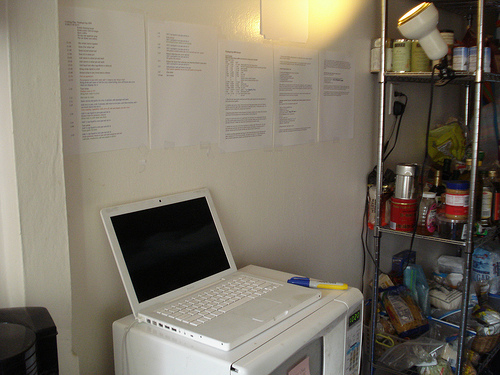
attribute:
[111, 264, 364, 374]
microwave — white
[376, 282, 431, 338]
bag — pasta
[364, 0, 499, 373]
rack — food storage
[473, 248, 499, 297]
sack — granulated sugar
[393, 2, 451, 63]
flood light — small, on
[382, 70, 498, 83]
shelf — top shelf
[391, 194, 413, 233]
can — red, coffee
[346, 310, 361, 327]
display — digital, 10:20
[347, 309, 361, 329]
display — timer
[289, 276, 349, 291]
pen — yellow and blue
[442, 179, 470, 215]
jar — peanut butter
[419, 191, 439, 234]
bottle — honey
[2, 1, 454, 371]
wall — white